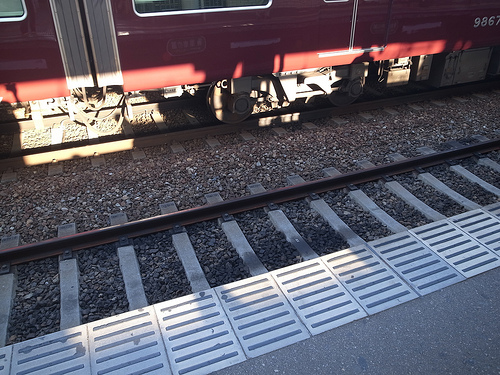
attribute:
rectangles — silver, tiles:
[5, 200, 499, 371]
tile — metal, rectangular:
[7, 324, 92, 374]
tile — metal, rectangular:
[86, 304, 172, 373]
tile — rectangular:
[152, 288, 249, 374]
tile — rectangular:
[213, 274, 312, 359]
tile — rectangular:
[270, 258, 370, 338]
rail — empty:
[0, 137, 499, 271]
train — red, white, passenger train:
[0, 0, 498, 126]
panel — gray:
[49, 1, 94, 90]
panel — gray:
[80, 1, 125, 89]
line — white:
[319, 0, 384, 57]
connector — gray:
[51, 0, 124, 91]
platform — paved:
[0, 202, 498, 374]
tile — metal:
[321, 244, 421, 317]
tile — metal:
[364, 230, 469, 298]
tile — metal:
[407, 220, 499, 280]